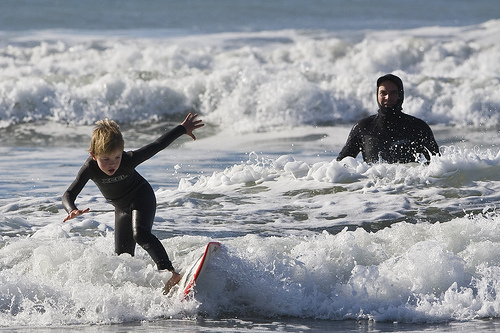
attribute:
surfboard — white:
[173, 235, 229, 305]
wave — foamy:
[14, 39, 496, 122]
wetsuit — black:
[334, 114, 429, 166]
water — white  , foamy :
[163, 46, 373, 260]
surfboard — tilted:
[145, 235, 220, 292]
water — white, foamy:
[222, 160, 499, 330]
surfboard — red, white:
[166, 238, 233, 308]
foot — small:
[164, 271, 185, 295]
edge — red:
[182, 241, 221, 303]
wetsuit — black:
[97, 180, 156, 236]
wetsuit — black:
[360, 121, 428, 149]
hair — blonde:
[82, 111, 137, 167]